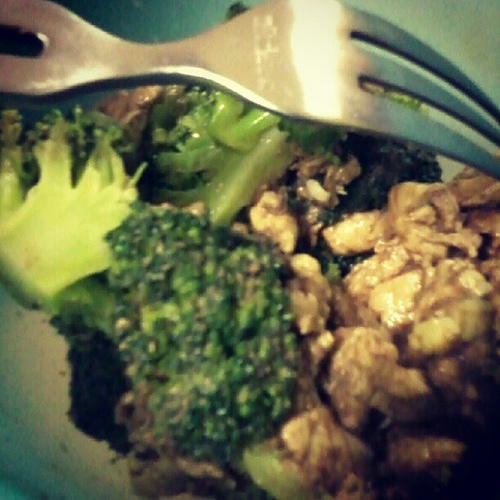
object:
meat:
[253, 169, 500, 497]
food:
[138, 164, 300, 278]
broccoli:
[0, 108, 141, 303]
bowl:
[134, 16, 168, 31]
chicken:
[359, 270, 397, 386]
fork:
[0, 0, 499, 182]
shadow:
[9, 40, 30, 52]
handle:
[0, 0, 150, 99]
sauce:
[294, 277, 314, 296]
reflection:
[307, 73, 350, 107]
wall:
[451, 1, 479, 24]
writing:
[262, 23, 286, 87]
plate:
[142, 24, 157, 31]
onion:
[91, 77, 158, 140]